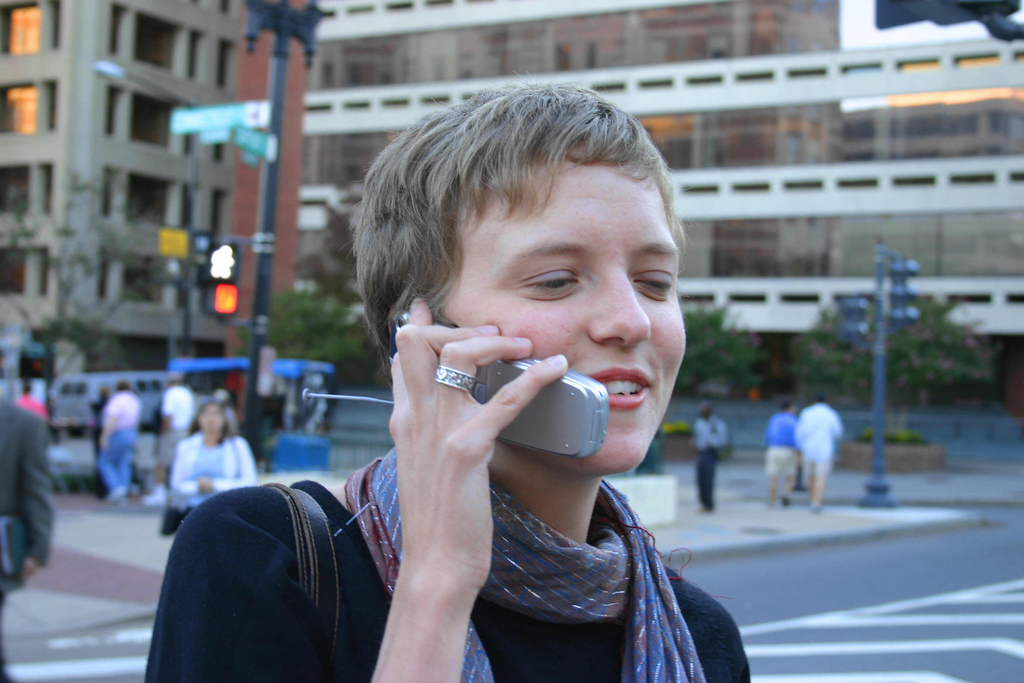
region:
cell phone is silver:
[390, 301, 610, 463]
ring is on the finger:
[426, 361, 475, 394]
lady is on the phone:
[138, 77, 752, 679]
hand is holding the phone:
[362, 290, 569, 679]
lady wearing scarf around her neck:
[144, 83, 762, 679]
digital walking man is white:
[207, 239, 236, 282]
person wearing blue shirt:
[763, 394, 799, 506]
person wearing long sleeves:
[794, 396, 849, 507]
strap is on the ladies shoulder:
[263, 480, 337, 649]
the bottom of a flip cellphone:
[494, 366, 611, 462]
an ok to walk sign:
[206, 241, 239, 281]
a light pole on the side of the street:
[241, 0, 314, 460]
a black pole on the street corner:
[839, 243, 917, 512]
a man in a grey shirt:
[691, 399, 727, 516]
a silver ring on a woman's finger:
[435, 363, 477, 393]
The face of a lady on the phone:
[476, 193, 689, 472]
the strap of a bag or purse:
[256, 481, 342, 679]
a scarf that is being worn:
[457, 471, 710, 680]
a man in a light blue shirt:
[794, 392, 849, 513]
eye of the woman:
[519, 252, 574, 300]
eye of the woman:
[627, 266, 675, 302]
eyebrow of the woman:
[533, 234, 594, 260]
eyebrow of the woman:
[608, 220, 688, 260]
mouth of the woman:
[580, 358, 660, 420]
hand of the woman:
[375, 315, 513, 620]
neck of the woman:
[513, 484, 627, 543]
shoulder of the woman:
[659, 584, 740, 645]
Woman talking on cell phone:
[141, 84, 759, 679]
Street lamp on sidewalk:
[829, 233, 931, 510]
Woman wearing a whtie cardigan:
[153, 394, 262, 538]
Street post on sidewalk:
[172, 1, 325, 469]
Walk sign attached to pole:
[201, 227, 244, 291]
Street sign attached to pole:
[156, 97, 278, 139]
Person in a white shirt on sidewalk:
[791, 385, 850, 513]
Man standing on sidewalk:
[684, 394, 741, 518]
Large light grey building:
[2, 1, 250, 438]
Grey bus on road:
[51, 365, 189, 439]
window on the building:
[895, 208, 934, 262]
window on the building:
[722, 211, 787, 262]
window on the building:
[715, 116, 776, 175]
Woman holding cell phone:
[158, 88, 785, 673]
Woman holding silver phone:
[189, 120, 782, 661]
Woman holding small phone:
[171, 113, 781, 661]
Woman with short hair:
[205, 110, 795, 667]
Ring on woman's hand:
[413, 347, 519, 421]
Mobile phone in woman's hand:
[364, 307, 621, 475]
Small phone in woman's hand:
[350, 306, 630, 475]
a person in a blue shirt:
[767, 407, 806, 505]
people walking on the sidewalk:
[63, 364, 256, 494]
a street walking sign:
[211, 234, 250, 304]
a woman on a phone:
[202, 81, 753, 679]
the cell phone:
[479, 347, 606, 447]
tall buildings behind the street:
[15, 13, 1017, 386]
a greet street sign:
[174, 102, 282, 154]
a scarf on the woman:
[351, 445, 707, 680]